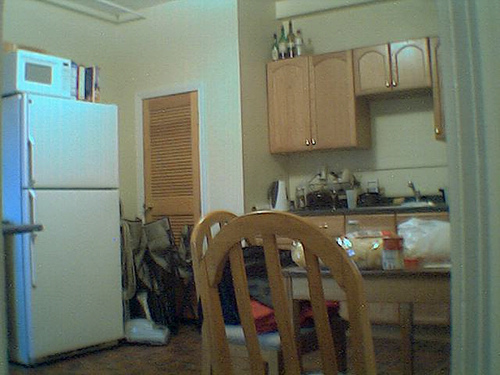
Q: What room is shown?
A: It is a kitchen.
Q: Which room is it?
A: It is a kitchen.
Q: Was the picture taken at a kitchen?
A: Yes, it was taken in a kitchen.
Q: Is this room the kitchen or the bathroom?
A: It is the kitchen.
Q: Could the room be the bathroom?
A: No, it is the kitchen.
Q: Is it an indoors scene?
A: Yes, it is indoors.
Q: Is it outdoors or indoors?
A: It is indoors.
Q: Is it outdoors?
A: No, it is indoors.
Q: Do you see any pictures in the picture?
A: No, there are no pictures.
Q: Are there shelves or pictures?
A: No, there are no pictures or shelves.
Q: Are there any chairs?
A: Yes, there is a chair.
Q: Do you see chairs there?
A: Yes, there is a chair.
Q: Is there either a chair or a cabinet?
A: Yes, there is a chair.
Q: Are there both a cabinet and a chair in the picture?
A: Yes, there are both a chair and a cabinet.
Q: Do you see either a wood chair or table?
A: Yes, there is a wood chair.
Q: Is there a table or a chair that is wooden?
A: Yes, the chair is wooden.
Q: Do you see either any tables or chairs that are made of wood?
A: Yes, the chair is made of wood.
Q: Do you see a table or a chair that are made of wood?
A: Yes, the chair is made of wood.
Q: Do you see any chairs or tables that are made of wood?
A: Yes, the chair is made of wood.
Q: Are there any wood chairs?
A: Yes, there is a wood chair.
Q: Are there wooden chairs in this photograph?
A: Yes, there is a wood chair.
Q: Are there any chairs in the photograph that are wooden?
A: Yes, there is a chair that is wooden.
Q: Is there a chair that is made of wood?
A: Yes, there is a chair that is made of wood.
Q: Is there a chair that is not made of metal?
A: Yes, there is a chair that is made of wood.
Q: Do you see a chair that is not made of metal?
A: Yes, there is a chair that is made of wood.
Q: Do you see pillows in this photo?
A: No, there are no pillows.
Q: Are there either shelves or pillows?
A: No, there are no pillows or shelves.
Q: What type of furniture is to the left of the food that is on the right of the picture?
A: The piece of furniture is a chair.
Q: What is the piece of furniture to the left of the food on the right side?
A: The piece of furniture is a chair.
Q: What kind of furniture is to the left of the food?
A: The piece of furniture is a chair.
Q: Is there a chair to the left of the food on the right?
A: Yes, there is a chair to the left of the food.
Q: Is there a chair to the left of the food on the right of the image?
A: Yes, there is a chair to the left of the food.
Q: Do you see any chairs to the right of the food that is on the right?
A: No, the chair is to the left of the food.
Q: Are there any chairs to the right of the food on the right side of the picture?
A: No, the chair is to the left of the food.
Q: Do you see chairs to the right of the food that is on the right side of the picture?
A: No, the chair is to the left of the food.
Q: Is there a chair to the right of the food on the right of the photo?
A: No, the chair is to the left of the food.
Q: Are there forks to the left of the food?
A: No, there is a chair to the left of the food.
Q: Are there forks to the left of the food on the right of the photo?
A: No, there is a chair to the left of the food.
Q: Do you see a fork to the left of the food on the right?
A: No, there is a chair to the left of the food.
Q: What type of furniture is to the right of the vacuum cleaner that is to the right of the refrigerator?
A: The piece of furniture is a chair.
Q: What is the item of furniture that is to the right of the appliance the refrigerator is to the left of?
A: The piece of furniture is a chair.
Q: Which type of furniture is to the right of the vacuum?
A: The piece of furniture is a chair.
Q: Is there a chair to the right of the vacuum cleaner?
A: Yes, there is a chair to the right of the vacuum cleaner.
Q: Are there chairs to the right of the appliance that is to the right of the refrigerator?
A: Yes, there is a chair to the right of the vacuum cleaner.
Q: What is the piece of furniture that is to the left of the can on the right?
A: The piece of furniture is a chair.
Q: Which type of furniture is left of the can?
A: The piece of furniture is a chair.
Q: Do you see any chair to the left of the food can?
A: Yes, there is a chair to the left of the can.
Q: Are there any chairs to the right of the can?
A: No, the chair is to the left of the can.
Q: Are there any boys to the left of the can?
A: No, there is a chair to the left of the can.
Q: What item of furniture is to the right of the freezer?
A: The piece of furniture is a chair.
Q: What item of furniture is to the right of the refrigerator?
A: The piece of furniture is a chair.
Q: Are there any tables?
A: Yes, there is a table.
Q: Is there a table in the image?
A: Yes, there is a table.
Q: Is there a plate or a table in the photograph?
A: Yes, there is a table.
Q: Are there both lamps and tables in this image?
A: No, there is a table but no lamps.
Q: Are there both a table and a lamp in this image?
A: No, there is a table but no lamps.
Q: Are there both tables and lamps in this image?
A: No, there is a table but no lamps.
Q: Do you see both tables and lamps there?
A: No, there is a table but no lamps.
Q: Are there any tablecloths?
A: No, there are no tablecloths.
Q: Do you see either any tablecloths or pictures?
A: No, there are no tablecloths or pictures.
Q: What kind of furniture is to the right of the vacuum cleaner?
A: The piece of furniture is a table.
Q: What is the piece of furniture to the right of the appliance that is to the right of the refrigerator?
A: The piece of furniture is a table.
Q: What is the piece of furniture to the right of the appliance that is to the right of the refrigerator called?
A: The piece of furniture is a table.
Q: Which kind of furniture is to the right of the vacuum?
A: The piece of furniture is a table.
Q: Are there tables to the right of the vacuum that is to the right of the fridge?
A: Yes, there is a table to the right of the vacuum cleaner.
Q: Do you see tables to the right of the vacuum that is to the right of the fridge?
A: Yes, there is a table to the right of the vacuum cleaner.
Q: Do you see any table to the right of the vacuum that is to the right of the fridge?
A: Yes, there is a table to the right of the vacuum cleaner.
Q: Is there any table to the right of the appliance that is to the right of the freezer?
A: Yes, there is a table to the right of the vacuum cleaner.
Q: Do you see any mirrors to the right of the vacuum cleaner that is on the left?
A: No, there is a table to the right of the vacuum.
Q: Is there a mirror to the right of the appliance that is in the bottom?
A: No, there is a table to the right of the vacuum.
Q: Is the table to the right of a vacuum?
A: Yes, the table is to the right of a vacuum.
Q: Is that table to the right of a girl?
A: No, the table is to the right of a vacuum.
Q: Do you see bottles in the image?
A: Yes, there is a bottle.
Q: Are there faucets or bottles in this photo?
A: Yes, there is a bottle.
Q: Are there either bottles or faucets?
A: Yes, there is a bottle.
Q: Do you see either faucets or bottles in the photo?
A: Yes, there is a bottle.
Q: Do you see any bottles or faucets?
A: Yes, there is a bottle.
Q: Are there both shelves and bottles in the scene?
A: No, there is a bottle but no shelves.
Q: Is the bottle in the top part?
A: Yes, the bottle is in the top of the image.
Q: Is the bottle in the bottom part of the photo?
A: No, the bottle is in the top of the image.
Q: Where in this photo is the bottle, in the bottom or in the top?
A: The bottle is in the top of the image.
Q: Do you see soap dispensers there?
A: No, there are no soap dispensers.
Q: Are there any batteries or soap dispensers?
A: No, there are no soap dispensers or batteries.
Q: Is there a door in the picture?
A: Yes, there is a door.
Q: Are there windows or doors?
A: Yes, there is a door.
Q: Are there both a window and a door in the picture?
A: No, there is a door but no windows.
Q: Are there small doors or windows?
A: Yes, there is a small door.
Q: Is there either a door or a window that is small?
A: Yes, the door is small.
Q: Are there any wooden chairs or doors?
A: Yes, there is a wood door.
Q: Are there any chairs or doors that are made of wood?
A: Yes, the door is made of wood.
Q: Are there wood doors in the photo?
A: Yes, there is a wood door.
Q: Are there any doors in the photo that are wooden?
A: Yes, there is a door that is wooden.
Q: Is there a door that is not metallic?
A: Yes, there is a wooden door.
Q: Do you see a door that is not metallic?
A: Yes, there is a wooden door.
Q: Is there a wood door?
A: Yes, there is a door that is made of wood.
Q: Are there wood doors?
A: Yes, there is a door that is made of wood.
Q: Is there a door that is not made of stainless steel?
A: Yes, there is a door that is made of wood.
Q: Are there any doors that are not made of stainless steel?
A: Yes, there is a door that is made of wood.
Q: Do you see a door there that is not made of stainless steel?
A: Yes, there is a door that is made of wood.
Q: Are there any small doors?
A: Yes, there is a small door.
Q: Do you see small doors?
A: Yes, there is a small door.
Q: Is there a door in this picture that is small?
A: Yes, there is a door that is small.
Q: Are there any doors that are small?
A: Yes, there is a door that is small.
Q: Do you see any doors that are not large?
A: Yes, there is a small door.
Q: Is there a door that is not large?
A: Yes, there is a small door.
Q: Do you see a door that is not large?
A: Yes, there is a small door.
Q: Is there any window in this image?
A: No, there are no windows.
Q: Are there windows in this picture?
A: No, there are no windows.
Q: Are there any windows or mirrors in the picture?
A: No, there are no windows or mirrors.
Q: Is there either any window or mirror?
A: No, there are no windows or mirrors.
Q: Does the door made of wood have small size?
A: Yes, the door is small.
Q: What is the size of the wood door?
A: The door is small.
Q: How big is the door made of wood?
A: The door is small.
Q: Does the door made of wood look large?
A: No, the door is small.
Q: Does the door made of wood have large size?
A: No, the door is small.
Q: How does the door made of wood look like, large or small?
A: The door is small.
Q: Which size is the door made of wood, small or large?
A: The door is small.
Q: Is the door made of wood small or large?
A: The door is small.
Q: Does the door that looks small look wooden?
A: Yes, the door is wooden.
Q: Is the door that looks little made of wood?
A: Yes, the door is made of wood.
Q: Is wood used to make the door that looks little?
A: Yes, the door is made of wood.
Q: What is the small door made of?
A: The door is made of wood.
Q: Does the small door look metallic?
A: No, the door is wooden.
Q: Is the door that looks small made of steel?
A: No, the door is made of wood.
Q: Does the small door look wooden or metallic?
A: The door is wooden.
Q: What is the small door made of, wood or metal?
A: The door is made of wood.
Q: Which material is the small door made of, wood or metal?
A: The door is made of wood.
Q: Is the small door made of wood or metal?
A: The door is made of wood.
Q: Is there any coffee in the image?
A: No, there is no coffee.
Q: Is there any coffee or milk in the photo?
A: No, there are no coffee or milk.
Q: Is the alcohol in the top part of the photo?
A: Yes, the alcohol is in the top of the image.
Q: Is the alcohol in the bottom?
A: No, the alcohol is in the top of the image.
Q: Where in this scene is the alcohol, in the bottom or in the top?
A: The alcohol is in the top of the image.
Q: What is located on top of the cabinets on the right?
A: The alcohol is on top of the cabinets.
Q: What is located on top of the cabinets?
A: The alcohol is on top of the cabinets.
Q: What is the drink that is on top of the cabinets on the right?
A: The drink is alcohol.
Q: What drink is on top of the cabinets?
A: The drink is alcohol.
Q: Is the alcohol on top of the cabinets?
A: Yes, the alcohol is on top of the cabinets.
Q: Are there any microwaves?
A: Yes, there is a microwave.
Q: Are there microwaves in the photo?
A: Yes, there is a microwave.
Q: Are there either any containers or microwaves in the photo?
A: Yes, there is a microwave.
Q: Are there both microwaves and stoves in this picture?
A: No, there is a microwave but no stoves.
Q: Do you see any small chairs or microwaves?
A: Yes, there is a small microwave.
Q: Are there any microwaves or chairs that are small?
A: Yes, the microwave is small.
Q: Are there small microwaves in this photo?
A: Yes, there is a small microwave.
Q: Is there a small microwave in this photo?
A: Yes, there is a small microwave.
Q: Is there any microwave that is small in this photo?
A: Yes, there is a small microwave.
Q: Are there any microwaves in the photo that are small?
A: Yes, there is a microwave that is small.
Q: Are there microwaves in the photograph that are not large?
A: Yes, there is a small microwave.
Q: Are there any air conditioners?
A: No, there are no air conditioners.